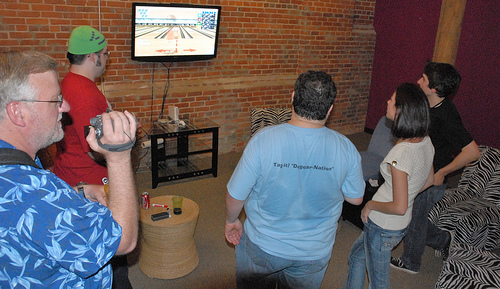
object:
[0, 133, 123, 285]
shirt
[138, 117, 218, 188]
tv stand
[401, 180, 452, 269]
jeans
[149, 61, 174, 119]
cords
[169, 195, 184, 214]
drink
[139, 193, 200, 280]
table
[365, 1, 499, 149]
wall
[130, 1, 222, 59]
television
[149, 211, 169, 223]
can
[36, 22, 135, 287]
man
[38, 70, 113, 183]
shirt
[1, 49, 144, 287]
man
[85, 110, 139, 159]
camera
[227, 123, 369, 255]
shirt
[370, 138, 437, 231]
blouse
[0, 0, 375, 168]
brick wall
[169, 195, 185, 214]
glass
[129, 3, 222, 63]
tv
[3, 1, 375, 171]
wall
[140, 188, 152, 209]
can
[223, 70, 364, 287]
man